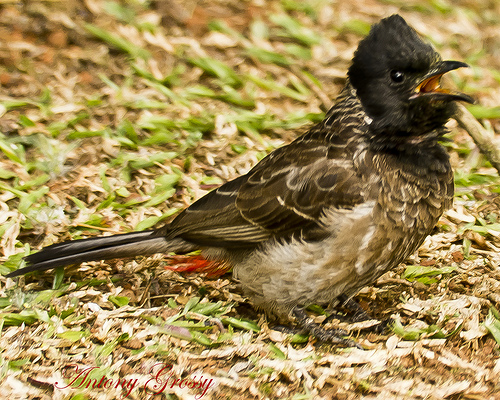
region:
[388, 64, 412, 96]
Bird has black eye.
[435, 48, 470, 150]
Bird has black beak.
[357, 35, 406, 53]
Bird has black head.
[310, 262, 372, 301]
Bird has gray stomach.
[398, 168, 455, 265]
Bird has brown chest.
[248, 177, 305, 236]
Bird has brown wing.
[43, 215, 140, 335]
Bird has black tail feathers.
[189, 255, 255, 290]
Bird has red feathers under tail.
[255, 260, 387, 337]
Bird is standing in the grass.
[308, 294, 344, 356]
Bird has black feet.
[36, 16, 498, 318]
Brown bird in grass area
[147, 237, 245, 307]
Red section of bird feathers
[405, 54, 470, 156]
Open beak of bird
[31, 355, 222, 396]
Photographer name for credit area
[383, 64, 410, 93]
Small black eye of bird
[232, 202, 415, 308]
Lighter colored stomach feathers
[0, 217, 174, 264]
Dark tail feathers on bird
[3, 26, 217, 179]
Green and brown grass area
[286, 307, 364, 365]
Thin bird's leg and foot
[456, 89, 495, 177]
Stick on ground in grass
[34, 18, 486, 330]
this is a bird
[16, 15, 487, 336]
the bird is short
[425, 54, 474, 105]
the beak is open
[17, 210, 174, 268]
the tail is long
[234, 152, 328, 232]
the feathers are folded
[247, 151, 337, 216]
the feather is brown in color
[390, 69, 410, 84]
the eye is black in color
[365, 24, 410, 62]
the head is black in color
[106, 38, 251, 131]
the leaves are green in color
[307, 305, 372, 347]
the feet are black in color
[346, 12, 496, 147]
face of the crow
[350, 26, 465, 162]
black face of the bird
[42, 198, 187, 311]
tail of the crow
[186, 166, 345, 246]
hair of the crow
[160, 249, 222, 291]
red hair of the crow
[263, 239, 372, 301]
white hair of the crow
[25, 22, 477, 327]
a green grass beside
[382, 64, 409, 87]
eye of the crow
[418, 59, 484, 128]
nose of the crow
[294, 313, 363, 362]
leg of the crow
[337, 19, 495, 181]
the head of a small bird.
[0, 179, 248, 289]
tail feathers on a bird.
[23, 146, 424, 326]
the right wing of a bird.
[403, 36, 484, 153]
a small bird beak.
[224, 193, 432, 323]
the front of a bird.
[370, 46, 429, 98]
a black bird eye.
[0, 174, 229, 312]
a long tail feather.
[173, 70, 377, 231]
the back of a small bird.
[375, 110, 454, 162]
the throat of a bird.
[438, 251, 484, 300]
a section of grass.